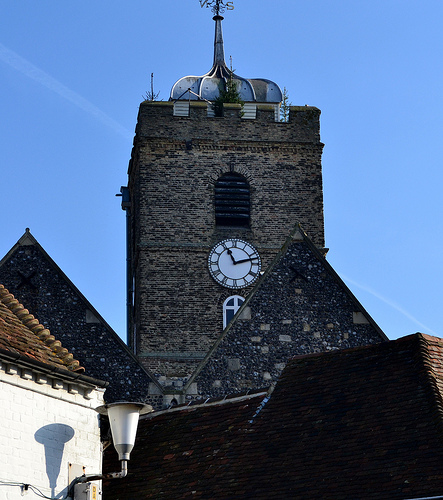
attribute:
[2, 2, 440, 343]
sky — blue,  blue 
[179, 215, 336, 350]
clock — round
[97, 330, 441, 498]
roof — brown, red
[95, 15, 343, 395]
tower — tall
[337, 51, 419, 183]
sky — blue, large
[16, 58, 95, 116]
clouds — white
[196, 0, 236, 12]
weather vane — silver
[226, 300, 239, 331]
window — blue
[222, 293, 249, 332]
trim — white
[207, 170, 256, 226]
window — brown, arched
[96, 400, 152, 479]
fixture — round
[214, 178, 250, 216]
slats — black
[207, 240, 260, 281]
time — 11:12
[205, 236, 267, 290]
clock — round